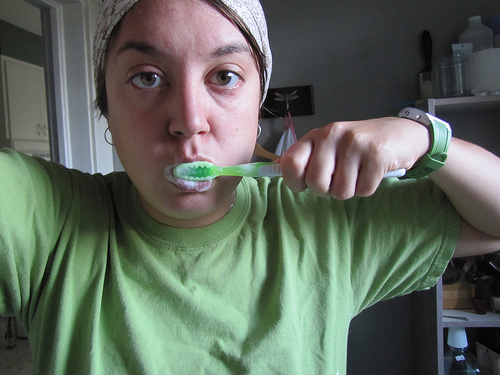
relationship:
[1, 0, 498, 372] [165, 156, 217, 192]
woman has mouth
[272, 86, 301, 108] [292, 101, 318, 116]
dragonfly on dark wood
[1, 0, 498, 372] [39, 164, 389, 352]
woman wearing a shirt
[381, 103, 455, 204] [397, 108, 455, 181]
watch on wrist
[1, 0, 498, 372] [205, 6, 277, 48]
woman wearing a bandana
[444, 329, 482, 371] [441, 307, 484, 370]
mouthwash on shelf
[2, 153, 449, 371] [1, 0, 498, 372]
shirt on woman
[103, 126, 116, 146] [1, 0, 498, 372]
earring on woman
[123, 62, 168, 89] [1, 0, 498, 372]
eye on woman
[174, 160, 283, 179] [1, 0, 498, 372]
teeth on woman